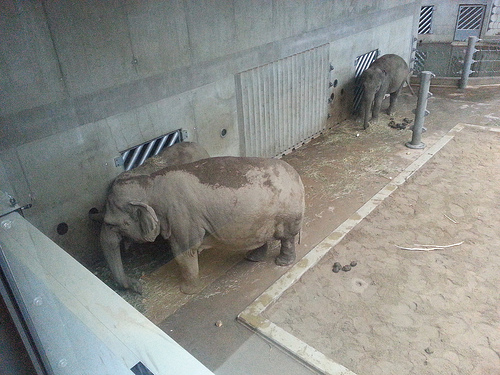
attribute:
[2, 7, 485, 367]
pen — concrete , cement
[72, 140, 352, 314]
elephant — gray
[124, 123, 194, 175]
bar — silver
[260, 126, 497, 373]
dirt — tan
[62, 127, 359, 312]
elephant — big, gray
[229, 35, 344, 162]
door — metal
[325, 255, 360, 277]
poop nuggets — nuggets 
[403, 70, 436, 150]
post — metal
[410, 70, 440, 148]
pole — metal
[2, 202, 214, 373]
wall — cement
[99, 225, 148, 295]
trunk — big, grey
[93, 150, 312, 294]
elephant — asian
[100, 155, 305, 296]
elephant — standing, up, big, grey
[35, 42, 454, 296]
cage — cement